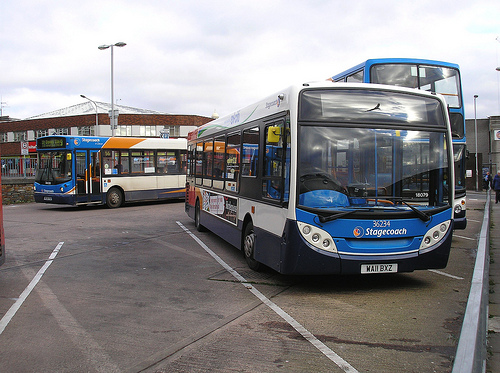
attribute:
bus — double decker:
[320, 52, 478, 240]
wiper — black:
[319, 194, 434, 230]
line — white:
[182, 221, 364, 366]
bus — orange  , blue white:
[23, 130, 190, 220]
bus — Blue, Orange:
[30, 137, 185, 205]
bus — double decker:
[360, 60, 470, 265]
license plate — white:
[360, 259, 400, 277]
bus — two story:
[345, 58, 468, 218]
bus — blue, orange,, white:
[34, 128, 188, 215]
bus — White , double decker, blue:
[183, 78, 455, 279]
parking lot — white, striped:
[0, 177, 497, 372]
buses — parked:
[34, 136, 186, 204]